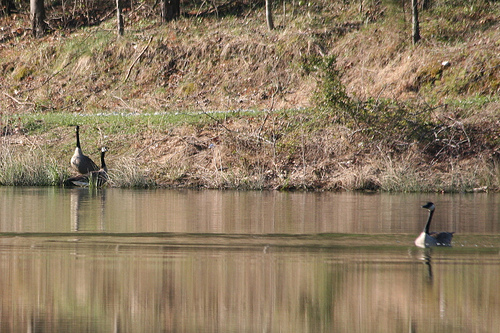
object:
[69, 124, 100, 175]
goose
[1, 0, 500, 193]
land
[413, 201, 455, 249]
bird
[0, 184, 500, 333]
water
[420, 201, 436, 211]
head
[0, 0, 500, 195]
grass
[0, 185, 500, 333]
ripples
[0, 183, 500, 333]
reflection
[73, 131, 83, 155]
neck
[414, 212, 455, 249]
body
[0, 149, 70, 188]
brush